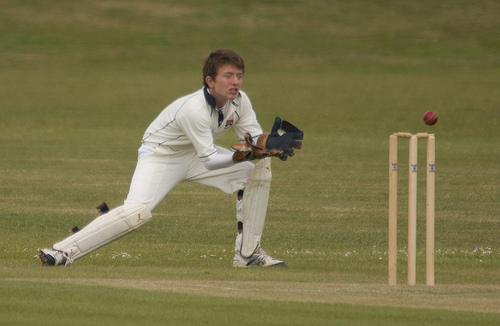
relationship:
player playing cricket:
[39, 48, 304, 269] [386, 133, 437, 294]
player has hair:
[39, 48, 304, 269] [205, 51, 245, 90]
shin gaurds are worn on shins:
[53, 158, 273, 257] [58, 189, 271, 252]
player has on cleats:
[39, 48, 304, 269] [40, 250, 285, 273]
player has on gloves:
[39, 48, 304, 269] [232, 116, 305, 163]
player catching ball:
[39, 48, 304, 269] [424, 112, 438, 126]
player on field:
[39, 48, 304, 269] [2, 3, 499, 325]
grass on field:
[0, 1, 499, 324] [2, 3, 499, 325]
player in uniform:
[39, 48, 304, 269] [56, 89, 274, 249]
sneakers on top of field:
[40, 250, 285, 273] [2, 3, 499, 325]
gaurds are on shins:
[53, 158, 273, 257] [58, 189, 271, 252]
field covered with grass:
[2, 3, 499, 325] [0, 1, 499, 324]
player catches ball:
[39, 48, 304, 269] [424, 112, 438, 126]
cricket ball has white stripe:
[424, 112, 438, 126] [428, 111, 435, 123]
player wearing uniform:
[39, 48, 304, 269] [56, 89, 274, 249]